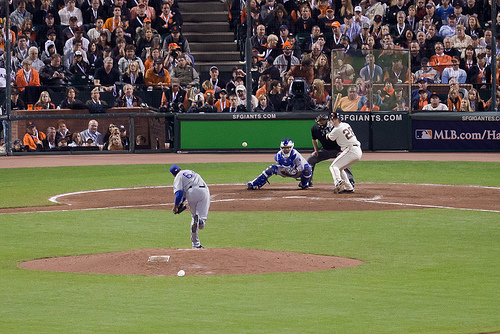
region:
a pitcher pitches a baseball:
[165, 130, 256, 254]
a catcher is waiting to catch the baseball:
[236, 132, 318, 192]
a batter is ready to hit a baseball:
[318, 90, 364, 197]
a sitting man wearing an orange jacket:
[20, 118, 46, 152]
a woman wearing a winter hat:
[41, 35, 61, 67]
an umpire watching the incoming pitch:
[300, 108, 356, 192]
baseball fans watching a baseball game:
[11, 0, 496, 112]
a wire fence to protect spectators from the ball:
[328, 41, 415, 116]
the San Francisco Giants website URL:
[334, 110, 407, 125]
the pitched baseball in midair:
[236, 137, 255, 152]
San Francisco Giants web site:
[226, 109, 413, 129]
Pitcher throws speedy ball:
[162, 129, 252, 254]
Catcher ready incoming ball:
[231, 102, 314, 205]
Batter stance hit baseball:
[324, 103, 371, 200]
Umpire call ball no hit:
[307, 96, 339, 178]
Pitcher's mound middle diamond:
[20, 246, 390, 290]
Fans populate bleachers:
[30, 21, 190, 96]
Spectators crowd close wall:
[191, 68, 302, 110]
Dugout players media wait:
[16, 118, 148, 150]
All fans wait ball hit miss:
[276, 1, 495, 53]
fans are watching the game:
[0, 0, 498, 112]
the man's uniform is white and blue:
[139, 147, 227, 249]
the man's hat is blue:
[164, 151, 185, 182]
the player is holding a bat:
[307, 96, 389, 204]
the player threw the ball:
[144, 153, 251, 269]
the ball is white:
[222, 124, 258, 156]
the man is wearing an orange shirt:
[14, 118, 51, 150]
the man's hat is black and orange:
[19, 119, 38, 136]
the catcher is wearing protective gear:
[234, 121, 346, 215]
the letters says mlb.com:
[399, 108, 485, 163]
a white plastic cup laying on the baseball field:
[167, 257, 201, 282]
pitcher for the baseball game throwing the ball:
[159, 153, 226, 257]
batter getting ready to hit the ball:
[320, 108, 371, 202]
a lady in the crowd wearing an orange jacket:
[8, 51, 42, 96]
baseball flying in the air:
[229, 125, 264, 161]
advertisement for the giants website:
[331, 99, 418, 135]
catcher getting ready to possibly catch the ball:
[226, 123, 320, 193]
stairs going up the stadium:
[170, 5, 258, 96]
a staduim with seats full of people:
[14, 3, 488, 110]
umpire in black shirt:
[302, 114, 358, 182]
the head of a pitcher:
[167, 158, 182, 178]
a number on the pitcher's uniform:
[177, 162, 198, 182]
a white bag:
[171, 260, 188, 280]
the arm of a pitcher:
[170, 172, 184, 212]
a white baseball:
[236, 136, 253, 149]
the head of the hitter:
[328, 108, 344, 129]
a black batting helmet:
[328, 108, 343, 121]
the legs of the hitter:
[326, 142, 361, 187]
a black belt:
[186, 182, 208, 193]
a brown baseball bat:
[326, 88, 344, 114]